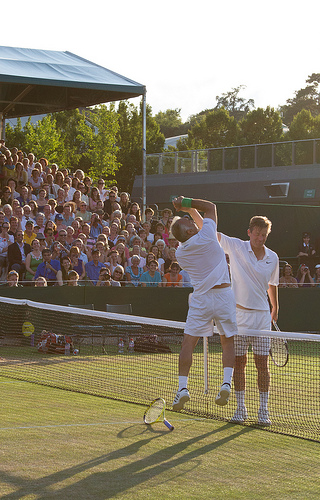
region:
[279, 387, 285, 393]
part of a fence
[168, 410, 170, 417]
part of a racket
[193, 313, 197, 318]
part of a short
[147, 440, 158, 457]
part of a shadow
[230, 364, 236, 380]
edge of a sock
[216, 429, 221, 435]
side of a lawn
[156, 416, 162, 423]
part of a racket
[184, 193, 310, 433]
this is a man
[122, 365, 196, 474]
this is a tennis racket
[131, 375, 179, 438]
the racket is on the ground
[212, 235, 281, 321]
man wearing a white shirt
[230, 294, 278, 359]
man wearing white shorts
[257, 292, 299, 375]
man holding a tennis racket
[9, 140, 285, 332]
people looking at the court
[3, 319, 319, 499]
tennis court is green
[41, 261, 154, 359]
chairs on the side of the court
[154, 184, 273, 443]
man is jumping up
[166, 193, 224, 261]
man wearing green wristband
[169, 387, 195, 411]
white and black tennis shoe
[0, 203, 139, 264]
audience at a tennis match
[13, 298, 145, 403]
tennis net during a match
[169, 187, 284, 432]
two tennis playes during a match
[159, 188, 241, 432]
tennis player jumping after a match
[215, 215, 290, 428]
tennis player holding racket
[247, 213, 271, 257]
tennis player looking down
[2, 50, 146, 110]
green stadium canopy at tennis match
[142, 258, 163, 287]
audience member in teal shirt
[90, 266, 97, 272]
man wearing blue shirt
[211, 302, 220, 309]
man wearing white shorts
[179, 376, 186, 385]
man wearing white socks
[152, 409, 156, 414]
inside of tennis racket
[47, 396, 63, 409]
green grass in court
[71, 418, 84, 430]
white line on court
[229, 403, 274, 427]
man wearing white sneakers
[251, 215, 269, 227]
man with brown hair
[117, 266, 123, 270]
woman with white hair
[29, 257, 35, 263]
woman wearing green dress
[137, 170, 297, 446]
two male tennis players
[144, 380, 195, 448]
a racket on the ground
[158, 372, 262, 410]
two feet in the air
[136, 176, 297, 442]
two men giving high fives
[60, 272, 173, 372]
two empty green chairs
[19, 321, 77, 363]
a red and gray bag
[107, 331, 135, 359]
two bottles of water with red caps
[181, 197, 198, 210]
a green sweatband at wrist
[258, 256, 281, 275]
a Nike emblem on shirt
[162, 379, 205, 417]
white shoes with black stripes